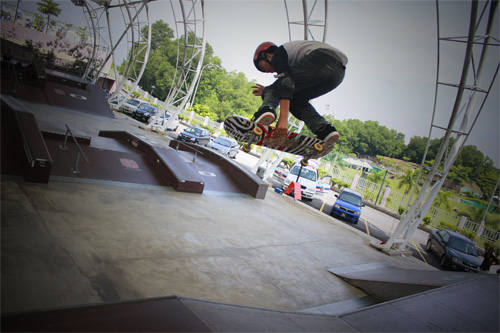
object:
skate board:
[223, 116, 334, 160]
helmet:
[253, 41, 279, 74]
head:
[253, 41, 277, 73]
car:
[425, 227, 483, 274]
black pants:
[250, 51, 346, 133]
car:
[132, 104, 159, 122]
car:
[331, 188, 365, 224]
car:
[270, 157, 332, 201]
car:
[206, 136, 239, 158]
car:
[177, 126, 210, 146]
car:
[148, 111, 179, 132]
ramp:
[52, 259, 499, 331]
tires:
[313, 143, 322, 151]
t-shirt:
[272, 40, 348, 75]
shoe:
[317, 125, 339, 144]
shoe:
[251, 108, 277, 125]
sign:
[282, 181, 302, 201]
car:
[282, 161, 318, 201]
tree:
[209, 65, 257, 120]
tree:
[118, 19, 196, 106]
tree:
[306, 113, 349, 151]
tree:
[347, 118, 369, 156]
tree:
[364, 120, 391, 158]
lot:
[104, 91, 484, 273]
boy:
[253, 39, 349, 143]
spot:
[411, 239, 484, 279]